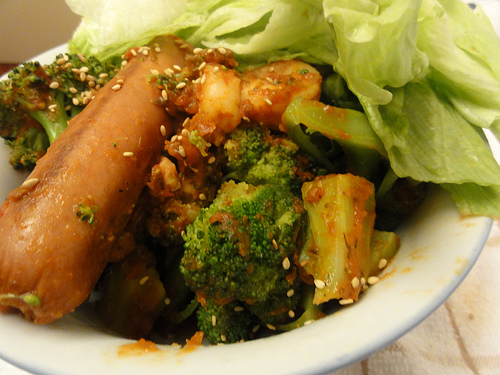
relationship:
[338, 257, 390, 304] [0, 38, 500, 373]
sesame seeds in white bowl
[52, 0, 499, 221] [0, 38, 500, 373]
lettuce in white bowl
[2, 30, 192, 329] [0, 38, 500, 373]
meat in white bowl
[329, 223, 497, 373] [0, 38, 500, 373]
cloth under white bowl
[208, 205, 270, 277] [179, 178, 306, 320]
seeds on broccoli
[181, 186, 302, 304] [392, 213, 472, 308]
broccoli in bowl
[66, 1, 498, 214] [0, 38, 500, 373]
cabbage in white bowl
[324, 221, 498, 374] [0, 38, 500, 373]
table cloth under white bowl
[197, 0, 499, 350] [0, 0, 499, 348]
vegetable on food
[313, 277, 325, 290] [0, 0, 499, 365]
seed in food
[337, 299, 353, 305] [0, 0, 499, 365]
seed in food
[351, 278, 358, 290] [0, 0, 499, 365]
seed in food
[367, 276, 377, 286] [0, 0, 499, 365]
seed in food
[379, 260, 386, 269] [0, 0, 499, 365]
seed in food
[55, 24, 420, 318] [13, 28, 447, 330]
food on plate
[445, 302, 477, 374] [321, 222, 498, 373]
line in table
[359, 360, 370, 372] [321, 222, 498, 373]
line in table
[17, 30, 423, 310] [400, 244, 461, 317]
vegetable on plate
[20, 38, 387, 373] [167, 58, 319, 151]
seeds on potatoes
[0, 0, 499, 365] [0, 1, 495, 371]
food in bowl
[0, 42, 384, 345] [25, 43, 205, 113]
broccoli with sesame seeds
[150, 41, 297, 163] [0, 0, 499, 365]
sauce on food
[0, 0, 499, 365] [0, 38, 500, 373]
food in white bowl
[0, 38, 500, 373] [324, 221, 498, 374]
white bowl on top of table cloth